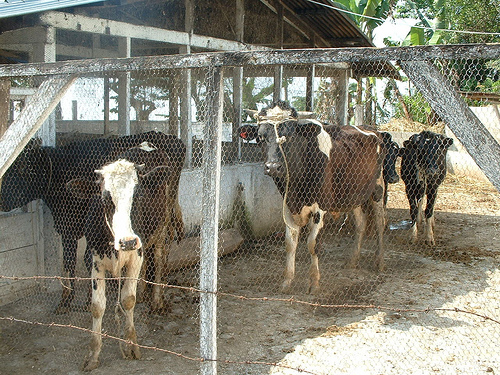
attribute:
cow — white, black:
[403, 129, 457, 244]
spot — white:
[308, 119, 369, 163]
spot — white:
[312, 123, 370, 161]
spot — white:
[302, 114, 339, 159]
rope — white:
[234, 101, 308, 223]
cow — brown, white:
[33, 142, 190, 317]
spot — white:
[305, 117, 333, 157]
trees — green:
[323, 2, 498, 129]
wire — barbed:
[7, 270, 495, 373]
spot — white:
[313, 129, 338, 161]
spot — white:
[314, 114, 334, 159]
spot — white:
[305, 114, 335, 162]